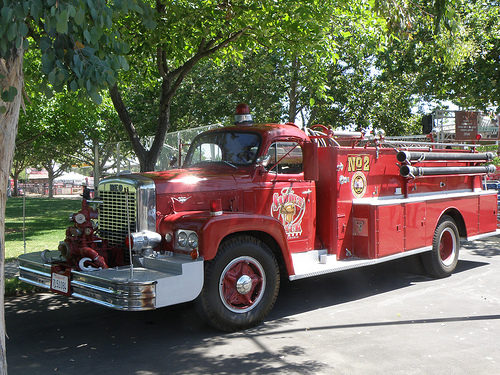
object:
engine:
[17, 104, 499, 333]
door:
[253, 137, 319, 254]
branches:
[242, 33, 297, 50]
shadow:
[0, 300, 327, 375]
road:
[0, 225, 500, 375]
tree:
[37, 0, 400, 174]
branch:
[171, 32, 223, 78]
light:
[234, 103, 253, 122]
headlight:
[176, 231, 199, 249]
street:
[0, 229, 500, 375]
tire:
[406, 214, 460, 278]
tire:
[193, 234, 281, 333]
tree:
[0, 0, 159, 214]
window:
[264, 141, 304, 174]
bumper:
[17, 253, 157, 313]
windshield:
[183, 131, 262, 169]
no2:
[348, 156, 370, 172]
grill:
[88, 178, 148, 238]